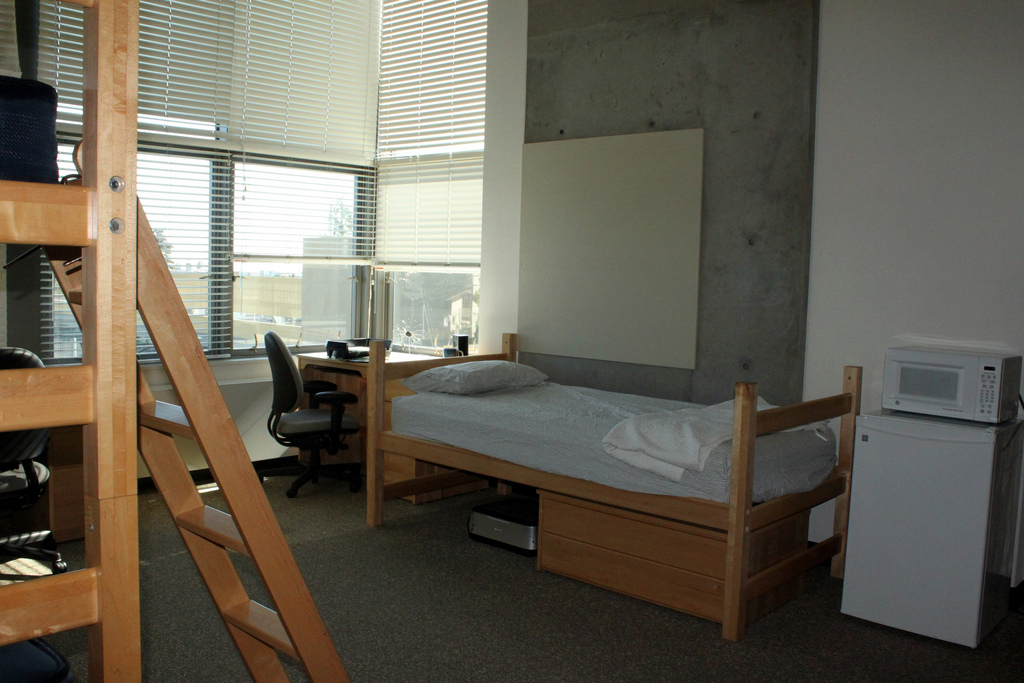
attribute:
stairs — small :
[131, 173, 413, 679]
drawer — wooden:
[529, 485, 735, 578]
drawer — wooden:
[521, 517, 742, 638]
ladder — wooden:
[30, 135, 342, 678]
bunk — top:
[7, 18, 70, 176]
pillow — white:
[410, 348, 549, 400]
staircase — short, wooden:
[33, 139, 356, 678]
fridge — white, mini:
[834, 407, 1018, 656]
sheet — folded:
[596, 383, 789, 479]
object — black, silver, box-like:
[456, 482, 545, 556]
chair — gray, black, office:
[253, 325, 372, 509]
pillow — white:
[398, 351, 550, 404]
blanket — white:
[594, 389, 778, 485]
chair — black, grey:
[259, 327, 370, 500]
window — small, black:
[220, 152, 376, 358]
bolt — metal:
[98, 161, 151, 196]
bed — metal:
[39, 156, 184, 440]